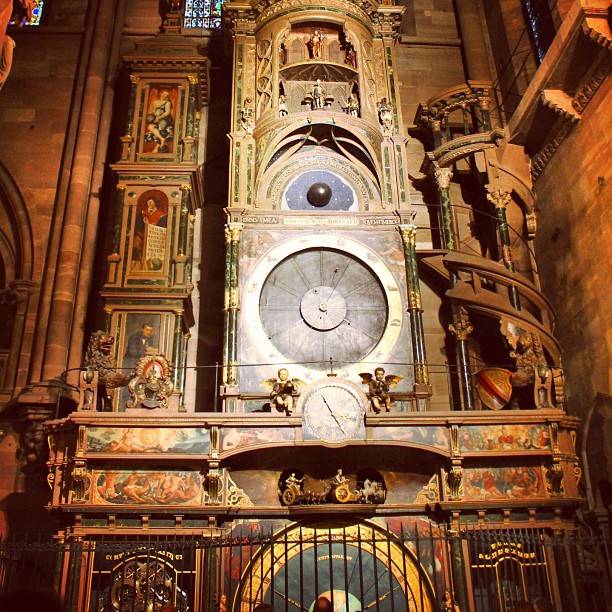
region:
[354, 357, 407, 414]
Cherub statue on the wall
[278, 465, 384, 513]
Statue of a horse and carriage on the wall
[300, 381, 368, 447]
Clock on the wall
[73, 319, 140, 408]
Lion statue on the platform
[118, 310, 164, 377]
Picture of a man on the wall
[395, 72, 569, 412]
Spiral staircase in the corner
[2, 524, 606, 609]
Black iron railing in front of the clock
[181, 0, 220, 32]
Window in the wall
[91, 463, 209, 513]
Mural on the wall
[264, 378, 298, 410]
item on the shelf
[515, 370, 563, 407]
item on the shelf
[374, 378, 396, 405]
item on the shelf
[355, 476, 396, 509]
item on the shelf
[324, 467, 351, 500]
item on the shelf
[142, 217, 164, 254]
item on the shelf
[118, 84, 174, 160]
item on the shelf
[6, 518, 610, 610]
A black iron fence.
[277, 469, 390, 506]
A figurine of a carriage and horses.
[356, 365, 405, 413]
A figurine of a cherub.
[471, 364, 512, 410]
A shield with a red sash.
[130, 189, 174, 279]
A painting of a man.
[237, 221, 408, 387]
Face of a very old clock.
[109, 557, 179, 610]
Round mechanism with gears.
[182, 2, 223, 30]
Blue, stained-glass window.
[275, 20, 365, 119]
Small figurines on a high shelf.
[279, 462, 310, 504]
decoration on the wall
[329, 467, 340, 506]
decoration on the wall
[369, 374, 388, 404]
decoration on the wall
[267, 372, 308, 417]
decoration on the wall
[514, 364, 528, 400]
decoration on the wall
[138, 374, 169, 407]
decoration on the wall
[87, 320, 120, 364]
decoration on the wall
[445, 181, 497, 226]
decoration on the wall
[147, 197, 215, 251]
decoration on the wall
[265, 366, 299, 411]
statue on the wall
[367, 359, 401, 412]
statue on the wall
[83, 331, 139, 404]
statue on the wall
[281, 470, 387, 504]
carvings on the wall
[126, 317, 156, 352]
picture of a guy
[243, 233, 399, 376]
circle on the wall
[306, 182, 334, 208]
the ball is brown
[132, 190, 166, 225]
picture of a person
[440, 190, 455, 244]
the rod is green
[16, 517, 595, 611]
black railing in front of the wall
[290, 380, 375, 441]
small clock above the railing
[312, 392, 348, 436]
hands on the small clock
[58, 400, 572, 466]
mantle the clock is attached to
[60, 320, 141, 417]
lion statue on the mantle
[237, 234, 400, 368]
clock face above the angel statues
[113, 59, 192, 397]
paintings above the mantle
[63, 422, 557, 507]
paintings on the mantle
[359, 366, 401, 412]
a small angel with wings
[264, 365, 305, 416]
a sitting angel with light colored hair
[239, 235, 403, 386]
a round clock with a dark face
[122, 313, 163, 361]
a square picture of a man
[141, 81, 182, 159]
the image of a woman wearing a dress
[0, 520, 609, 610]
railing in front of the clock tower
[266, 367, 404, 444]
a small round clock with an angel on each side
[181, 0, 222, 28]
a small window at the top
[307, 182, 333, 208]
a round black ball